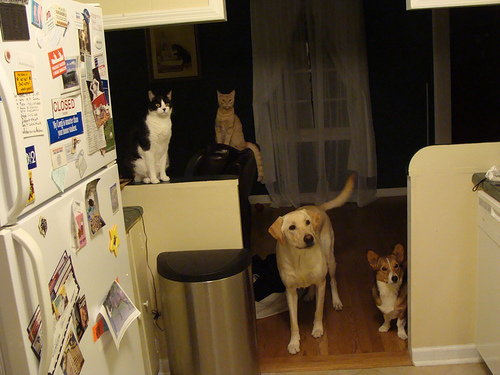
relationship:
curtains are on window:
[251, 0, 375, 205] [272, 2, 351, 143]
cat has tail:
[213, 89, 263, 184] [249, 143, 264, 182]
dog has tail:
[267, 170, 355, 355] [322, 174, 357, 209]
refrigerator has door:
[0, 4, 146, 374] [1, 2, 118, 222]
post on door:
[19, 94, 42, 135] [1, 2, 118, 222]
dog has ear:
[367, 244, 409, 338] [367, 248, 379, 267]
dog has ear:
[367, 244, 409, 338] [393, 245, 406, 262]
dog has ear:
[267, 170, 355, 355] [270, 216, 284, 241]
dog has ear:
[267, 170, 355, 355] [302, 209, 326, 231]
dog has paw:
[367, 244, 409, 338] [379, 324, 389, 331]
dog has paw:
[367, 244, 409, 338] [399, 330, 408, 340]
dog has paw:
[267, 170, 355, 355] [289, 340, 302, 354]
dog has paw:
[267, 170, 355, 355] [310, 324, 325, 337]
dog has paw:
[267, 170, 355, 355] [334, 300, 343, 308]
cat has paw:
[123, 88, 176, 184] [150, 178, 161, 185]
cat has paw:
[123, 88, 176, 184] [162, 176, 173, 183]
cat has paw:
[123, 88, 176, 184] [144, 179, 150, 183]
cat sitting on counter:
[123, 88, 176, 184] [122, 146, 255, 358]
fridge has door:
[0, 4, 146, 374] [1, 2, 118, 222]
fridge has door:
[0, 4, 146, 374] [0, 166, 140, 373]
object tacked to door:
[72, 205, 86, 249] [0, 166, 140, 373]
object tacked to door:
[110, 227, 117, 254] [0, 166, 140, 373]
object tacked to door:
[93, 278, 139, 353] [0, 166, 140, 373]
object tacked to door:
[47, 99, 84, 141] [1, 2, 118, 222]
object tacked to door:
[45, 48, 68, 77] [1, 2, 118, 222]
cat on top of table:
[213, 89, 263, 184] [122, 146, 255, 358]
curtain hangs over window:
[251, 0, 375, 205] [272, 2, 351, 143]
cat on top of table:
[123, 88, 176, 184] [122, 146, 255, 358]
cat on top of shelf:
[123, 88, 176, 184] [122, 146, 255, 358]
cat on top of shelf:
[213, 89, 263, 184] [122, 146, 255, 358]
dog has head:
[367, 244, 409, 338] [375, 253, 408, 286]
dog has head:
[267, 170, 355, 355] [281, 213, 319, 252]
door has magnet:
[1, 2, 118, 222] [16, 71, 34, 92]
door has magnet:
[1, 2, 118, 222] [45, 48, 68, 77]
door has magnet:
[1, 2, 118, 222] [32, 3, 41, 27]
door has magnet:
[0, 166, 140, 373] [39, 218, 46, 234]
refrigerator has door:
[0, 4, 146, 374] [0, 166, 140, 373]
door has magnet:
[0, 166, 140, 373] [107, 229, 124, 252]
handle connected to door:
[0, 66, 33, 222] [1, 2, 118, 222]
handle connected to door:
[8, 229, 55, 373] [0, 166, 140, 373]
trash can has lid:
[158, 248, 258, 373] [156, 249, 252, 284]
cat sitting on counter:
[213, 89, 263, 184] [122, 146, 255, 358]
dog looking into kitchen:
[367, 244, 409, 338] [122, 144, 499, 373]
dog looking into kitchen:
[267, 170, 355, 355] [122, 144, 499, 373]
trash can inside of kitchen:
[158, 248, 258, 373] [122, 144, 499, 373]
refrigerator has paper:
[0, 4, 146, 374] [93, 278, 139, 353]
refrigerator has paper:
[0, 4, 146, 374] [87, 178, 105, 236]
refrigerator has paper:
[0, 4, 146, 374] [54, 165, 67, 192]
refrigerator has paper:
[0, 4, 146, 374] [19, 94, 42, 135]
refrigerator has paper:
[0, 4, 146, 374] [79, 72, 108, 153]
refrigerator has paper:
[0, 4, 146, 374] [59, 335, 84, 374]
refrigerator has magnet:
[0, 4, 146, 374] [16, 71, 34, 92]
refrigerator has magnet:
[0, 4, 146, 374] [39, 218, 46, 234]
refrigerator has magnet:
[0, 4, 146, 374] [107, 229, 124, 252]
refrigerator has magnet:
[0, 4, 146, 374] [32, 3, 41, 27]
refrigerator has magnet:
[0, 4, 146, 374] [6, 51, 12, 62]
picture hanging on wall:
[144, 24, 201, 84] [105, 1, 497, 188]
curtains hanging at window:
[251, 0, 375, 205] [272, 2, 351, 143]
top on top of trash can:
[156, 249, 252, 284] [158, 248, 258, 373]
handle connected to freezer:
[0, 66, 33, 222] [1, 2, 118, 222]